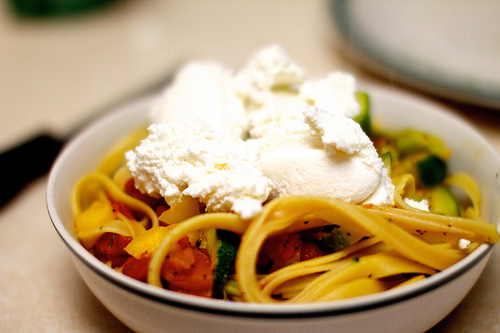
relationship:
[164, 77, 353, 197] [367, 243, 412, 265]
cheese on pasta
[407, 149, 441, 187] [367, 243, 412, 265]
broccoli in pasta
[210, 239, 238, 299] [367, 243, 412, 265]
vegetables in pasta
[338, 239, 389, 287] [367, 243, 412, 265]
flecks on pasta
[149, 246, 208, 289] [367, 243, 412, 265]
tomato in pasta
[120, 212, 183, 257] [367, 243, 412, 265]
yellow peppers in pasta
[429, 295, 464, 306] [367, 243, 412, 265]
bowl of pasta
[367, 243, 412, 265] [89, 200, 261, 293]
pasta and vegetables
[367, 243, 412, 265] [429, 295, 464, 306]
pasta in bowl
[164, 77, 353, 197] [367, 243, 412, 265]
cheese on top of pasta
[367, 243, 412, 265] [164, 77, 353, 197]
pasta topped with cheese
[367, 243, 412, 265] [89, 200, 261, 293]
pasta with vegetables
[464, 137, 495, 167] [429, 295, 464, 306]
sauce on bowl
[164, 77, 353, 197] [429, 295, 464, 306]
cheese in bowl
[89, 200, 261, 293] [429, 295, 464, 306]
vegetables in bowl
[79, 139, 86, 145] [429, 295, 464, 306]
edge of bowl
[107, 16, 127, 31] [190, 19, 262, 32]
part of table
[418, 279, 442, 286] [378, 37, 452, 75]
stripe on plate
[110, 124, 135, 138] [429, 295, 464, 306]
inside of bowl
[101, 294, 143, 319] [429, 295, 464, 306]
side of bowl